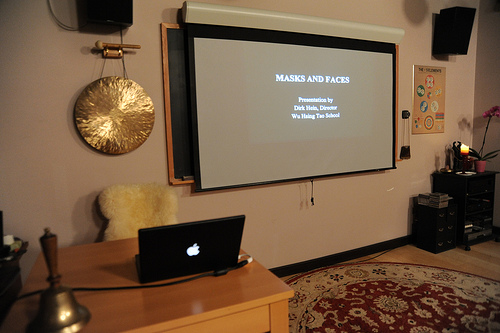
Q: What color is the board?
A: Black.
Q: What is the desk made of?
A: Wood.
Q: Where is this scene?
A: Living room.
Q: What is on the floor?
A: Rug.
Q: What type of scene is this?
A: Indoor.